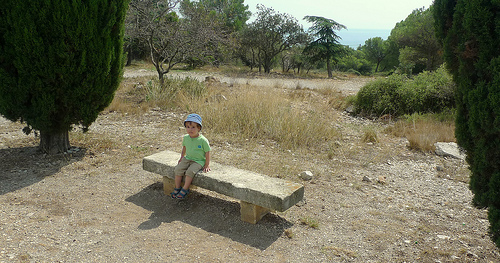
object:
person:
[168, 113, 216, 201]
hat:
[183, 113, 204, 129]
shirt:
[178, 133, 213, 168]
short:
[173, 157, 204, 176]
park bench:
[140, 146, 304, 224]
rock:
[300, 170, 316, 180]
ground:
[0, 55, 500, 262]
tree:
[301, 12, 346, 81]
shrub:
[136, 76, 204, 113]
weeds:
[360, 125, 378, 143]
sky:
[168, 0, 434, 51]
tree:
[227, 3, 308, 74]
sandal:
[174, 188, 190, 199]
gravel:
[359, 174, 378, 184]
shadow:
[124, 180, 296, 251]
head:
[182, 113, 205, 137]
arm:
[199, 138, 213, 166]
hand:
[201, 164, 213, 172]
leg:
[175, 162, 207, 199]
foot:
[176, 189, 190, 199]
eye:
[186, 125, 192, 129]